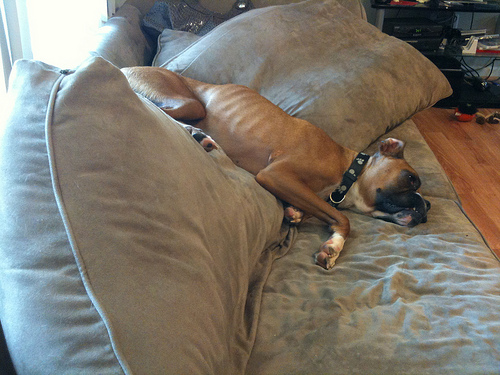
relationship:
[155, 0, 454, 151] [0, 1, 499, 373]
cushion over couch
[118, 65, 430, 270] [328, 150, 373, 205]
boxer has collar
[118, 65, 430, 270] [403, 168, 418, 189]
boxer has eye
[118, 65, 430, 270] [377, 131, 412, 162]
boxer has ear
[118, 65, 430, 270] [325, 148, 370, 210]
boxer with collar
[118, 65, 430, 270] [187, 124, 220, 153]
boxer with paw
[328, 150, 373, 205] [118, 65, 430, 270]
collar on boxer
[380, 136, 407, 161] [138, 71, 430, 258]
ear on boxer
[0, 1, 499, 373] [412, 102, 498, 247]
couch on floor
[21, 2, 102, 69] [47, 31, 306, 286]
window behind couch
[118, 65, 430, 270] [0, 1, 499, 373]
boxer laying on couch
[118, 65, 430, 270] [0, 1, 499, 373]
boxer lying on couch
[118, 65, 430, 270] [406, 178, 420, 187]
boxer with eye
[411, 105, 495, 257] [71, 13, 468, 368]
floor next to couch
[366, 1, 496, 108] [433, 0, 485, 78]
entertainment system on table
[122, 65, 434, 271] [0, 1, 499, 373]
boxer on couch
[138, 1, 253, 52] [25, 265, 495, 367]
denim on couch